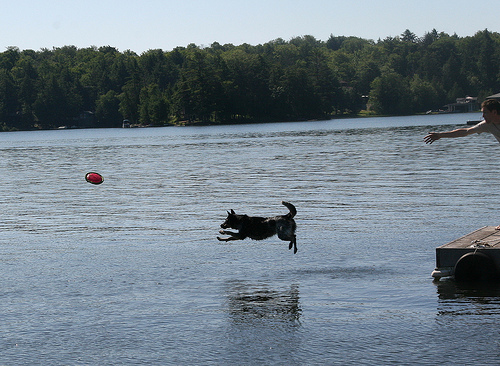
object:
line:
[0, 28, 500, 129]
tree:
[359, 63, 414, 112]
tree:
[276, 62, 324, 117]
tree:
[219, 56, 256, 115]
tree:
[167, 52, 216, 127]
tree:
[138, 80, 173, 124]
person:
[423, 100, 500, 145]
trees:
[2, 48, 39, 129]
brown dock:
[430, 225, 499, 283]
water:
[1, 308, 112, 364]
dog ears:
[227, 211, 231, 216]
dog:
[217, 201, 298, 255]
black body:
[216, 201, 298, 254]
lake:
[154, 136, 390, 191]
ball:
[85, 172, 104, 185]